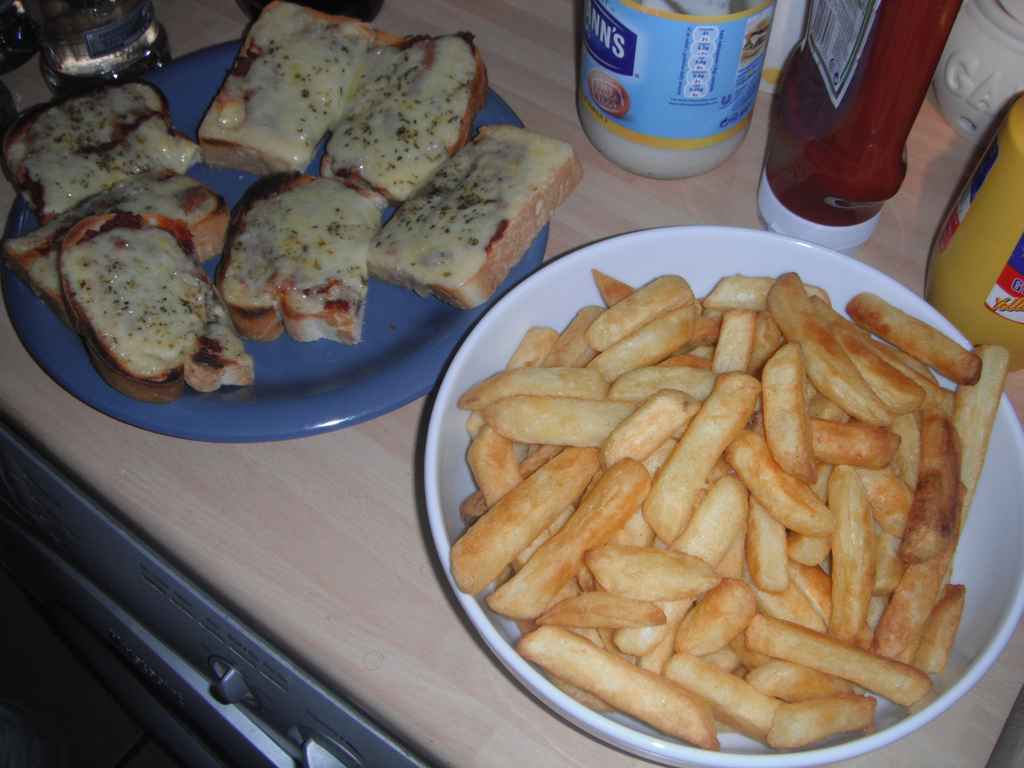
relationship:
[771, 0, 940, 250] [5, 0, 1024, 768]
ketchup on plate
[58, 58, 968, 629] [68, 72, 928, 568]
food on plate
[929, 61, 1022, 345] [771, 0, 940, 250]
mustard near ketchup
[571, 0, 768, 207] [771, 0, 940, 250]
mayo near ketchup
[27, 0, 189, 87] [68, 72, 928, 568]
glass near plate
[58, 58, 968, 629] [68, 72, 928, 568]
food on top of plate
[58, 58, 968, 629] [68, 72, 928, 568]
food on white plate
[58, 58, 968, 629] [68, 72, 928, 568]
food on porcelain plate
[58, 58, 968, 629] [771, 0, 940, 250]
food near ketchup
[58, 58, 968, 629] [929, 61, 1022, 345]
food near mustard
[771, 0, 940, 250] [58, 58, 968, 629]
ketchup near food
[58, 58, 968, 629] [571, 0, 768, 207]
food near mayo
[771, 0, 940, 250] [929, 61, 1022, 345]
ketchup near mustard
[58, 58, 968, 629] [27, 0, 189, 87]
food near glass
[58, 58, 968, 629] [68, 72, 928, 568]
food near plate